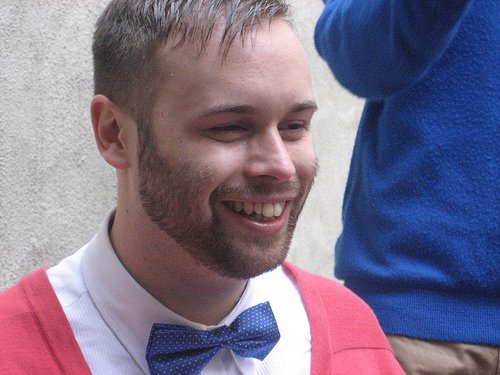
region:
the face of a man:
[191, 63, 318, 268]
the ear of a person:
[88, 89, 130, 171]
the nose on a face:
[246, 137, 299, 185]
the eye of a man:
[282, 105, 317, 142]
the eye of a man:
[199, 112, 256, 142]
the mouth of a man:
[217, 190, 299, 228]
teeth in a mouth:
[247, 203, 282, 219]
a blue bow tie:
[141, 298, 282, 374]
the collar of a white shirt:
[81, 245, 136, 332]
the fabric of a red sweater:
[305, 270, 390, 373]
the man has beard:
[134, 94, 324, 303]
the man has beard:
[169, 157, 351, 292]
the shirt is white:
[64, 271, 150, 357]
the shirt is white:
[261, 289, 308, 371]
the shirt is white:
[81, 282, 178, 373]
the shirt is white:
[176, 312, 237, 373]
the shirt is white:
[216, 290, 286, 366]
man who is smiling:
[1, 4, 421, 374]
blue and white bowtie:
[144, 300, 286, 374]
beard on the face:
[129, 131, 326, 281]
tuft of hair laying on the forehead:
[209, 10, 264, 71]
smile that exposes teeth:
[221, 197, 296, 232]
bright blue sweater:
[319, 2, 497, 347]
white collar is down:
[75, 251, 193, 373]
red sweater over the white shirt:
[2, 243, 410, 374]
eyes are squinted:
[208, 116, 318, 143]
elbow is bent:
[305, 1, 475, 109]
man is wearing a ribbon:
[87, 147, 284, 367]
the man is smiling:
[96, 25, 330, 291]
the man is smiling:
[138, 96, 315, 253]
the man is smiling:
[147, 102, 351, 341]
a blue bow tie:
[146, 327, 286, 354]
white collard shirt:
[97, 275, 139, 317]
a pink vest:
[326, 304, 378, 371]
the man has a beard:
[140, 178, 192, 230]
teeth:
[244, 205, 284, 222]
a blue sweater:
[380, 127, 496, 259]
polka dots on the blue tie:
[152, 324, 282, 369]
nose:
[255, 132, 297, 180]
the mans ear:
[97, 91, 134, 165]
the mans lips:
[247, 223, 283, 233]